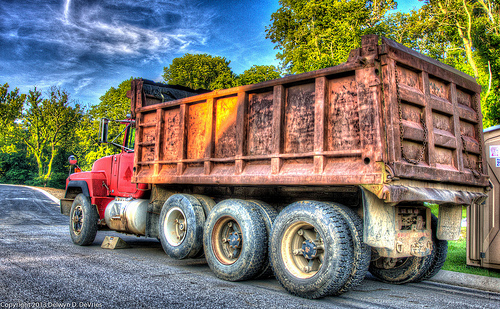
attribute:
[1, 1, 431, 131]
sky — blue, cloudy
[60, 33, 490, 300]
dump truck — large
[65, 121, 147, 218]
truck cab — red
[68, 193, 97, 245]
tire — middle, rear, the front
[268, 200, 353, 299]
tire — back, dirty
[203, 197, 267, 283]
tire — rear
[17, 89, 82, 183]
tree — in distance, bright green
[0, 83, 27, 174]
tree — in distance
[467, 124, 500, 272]
toilet — portable, brown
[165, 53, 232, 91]
tree — in distance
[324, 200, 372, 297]
tire — back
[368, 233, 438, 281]
tire — back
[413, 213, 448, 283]
tire — back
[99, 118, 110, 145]
mirror — side, rearview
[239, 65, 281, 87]
leaves — green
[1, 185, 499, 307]
road — grey, gray